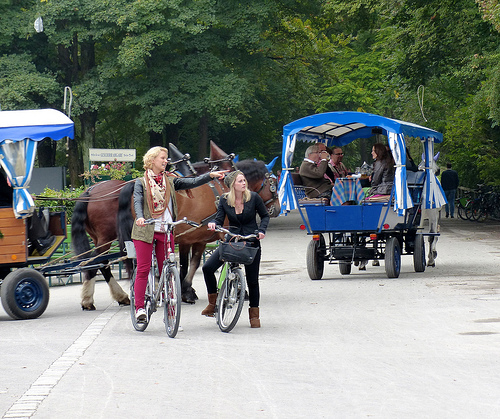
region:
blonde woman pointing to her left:
[107, 142, 230, 341]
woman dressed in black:
[193, 162, 275, 353]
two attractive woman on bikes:
[106, 135, 283, 345]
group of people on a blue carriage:
[278, 94, 458, 283]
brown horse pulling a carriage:
[0, 80, 287, 322]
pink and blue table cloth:
[318, 167, 372, 216]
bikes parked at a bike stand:
[448, 163, 498, 224]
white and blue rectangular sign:
[82, 142, 141, 172]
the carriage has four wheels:
[280, 218, 456, 303]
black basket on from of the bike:
[202, 228, 273, 270]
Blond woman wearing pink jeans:
[121, 142, 231, 333]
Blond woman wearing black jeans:
[198, 165, 273, 331]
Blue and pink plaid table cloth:
[325, 170, 366, 205]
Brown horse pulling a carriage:
[65, 150, 280, 312]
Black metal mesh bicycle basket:
[215, 232, 262, 267]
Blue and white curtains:
[381, 122, 447, 212]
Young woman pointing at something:
[125, 141, 230, 321]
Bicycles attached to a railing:
[450, 180, 496, 221]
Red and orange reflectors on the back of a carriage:
[295, 217, 395, 239]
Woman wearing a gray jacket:
[358, 138, 400, 203]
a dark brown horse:
[79, 150, 277, 312]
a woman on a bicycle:
[126, 145, 222, 335]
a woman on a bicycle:
[197, 170, 267, 333]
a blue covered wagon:
[279, 107, 435, 277]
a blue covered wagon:
[0, 99, 82, 316]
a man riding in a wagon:
[300, 142, 334, 196]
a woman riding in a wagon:
[361, 141, 393, 194]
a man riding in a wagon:
[324, 144, 349, 174]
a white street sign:
[82, 144, 134, 164]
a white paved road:
[29, 205, 491, 412]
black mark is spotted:
[467, 328, 477, 340]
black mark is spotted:
[459, 326, 475, 343]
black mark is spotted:
[472, 322, 479, 340]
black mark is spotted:
[478, 323, 484, 340]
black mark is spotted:
[463, 326, 473, 338]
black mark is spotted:
[476, 326, 486, 341]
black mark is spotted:
[464, 331, 478, 336]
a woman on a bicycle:
[174, 154, 299, 380]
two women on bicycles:
[98, 144, 366, 365]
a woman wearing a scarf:
[117, 135, 193, 227]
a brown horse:
[117, 129, 298, 266]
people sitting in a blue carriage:
[263, 102, 460, 287]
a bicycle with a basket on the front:
[193, 157, 283, 329]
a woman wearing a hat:
[202, 151, 289, 263]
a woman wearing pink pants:
[108, 146, 217, 316]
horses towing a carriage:
[13, 112, 335, 315]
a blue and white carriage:
[264, 100, 496, 295]